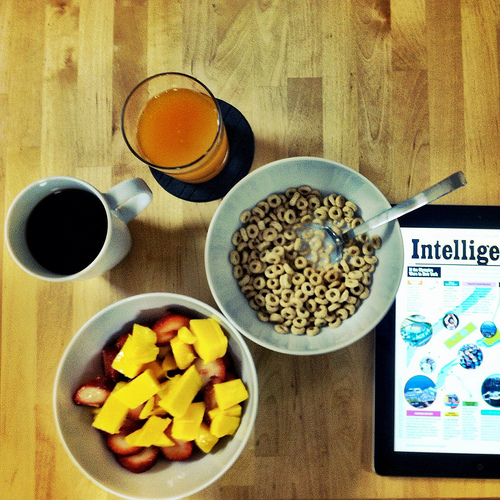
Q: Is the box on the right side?
A: Yes, the box is on the right of the image.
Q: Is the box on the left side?
A: No, the box is on the right of the image.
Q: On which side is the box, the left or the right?
A: The box is on the right of the image.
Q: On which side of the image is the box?
A: The box is on the right of the image.